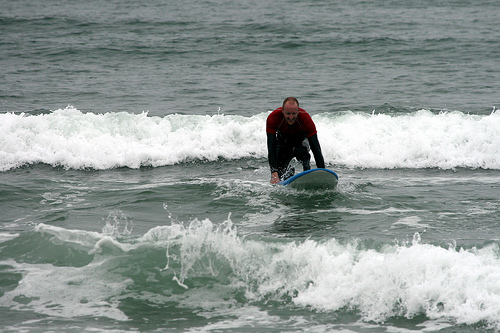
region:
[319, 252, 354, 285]
WHITE SEA FOAM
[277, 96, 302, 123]
MAN'S BALD HEAD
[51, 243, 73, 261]
GREEN GREY SEA WATER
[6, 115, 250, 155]
BREAKING OCEAN WAVE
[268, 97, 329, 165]
MAN KNEELING IN CROUCHED POSITION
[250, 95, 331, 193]
MAN KNEELING IN CROUCHED POSITION ON SURF BOARD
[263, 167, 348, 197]
BLUE AND GREY SURF BOARD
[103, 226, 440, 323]
WAVE ROLLING INTO BEACH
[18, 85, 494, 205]
MAN SURFING IN THE OCEAN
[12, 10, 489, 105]
RIPPLES IN THE OCEAN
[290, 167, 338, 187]
blue stripe on front of surfboard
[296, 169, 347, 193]
white bottom of surfboard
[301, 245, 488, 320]
foamy white waves in front right of pictures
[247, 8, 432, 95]
blue grey water in upper right of photo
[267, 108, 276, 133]
man's right arm in red /black wetsuit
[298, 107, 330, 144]
man's left arm in red /black wetsuit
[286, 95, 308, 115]
man with receding hairline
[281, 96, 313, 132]
man's smiling face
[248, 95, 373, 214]
smiling man kneeling on surfboard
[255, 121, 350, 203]
red and black wetsuit worn by man on surfboard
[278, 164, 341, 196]
a blue and white surfboard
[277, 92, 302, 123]
the balding head of a man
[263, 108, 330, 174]
a red and black wetsuit on a man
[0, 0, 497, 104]
dark ocean water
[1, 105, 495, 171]
a white wave rolling in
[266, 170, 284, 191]
a bare hand holding a surfboard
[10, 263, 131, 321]
white foam on the water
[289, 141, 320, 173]
the bent knee of a surfer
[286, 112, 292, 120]
the nose of a surfer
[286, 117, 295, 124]
the smiling mouth of a surfer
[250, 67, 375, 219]
Man surfing on the ocean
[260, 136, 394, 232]
Surfboard is white and blue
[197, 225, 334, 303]
White cap on ocean waves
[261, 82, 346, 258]
Man wearing full body wetsuit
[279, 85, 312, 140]
Man is going bald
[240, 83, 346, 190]
Surfer is trying to stand on the board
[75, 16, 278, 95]
Background of ocean is flat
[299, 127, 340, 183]
Man wearing long sleeves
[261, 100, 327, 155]
Red short sleeve on man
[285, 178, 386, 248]
Shadow from the surfboard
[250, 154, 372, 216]
a blue and white surfboard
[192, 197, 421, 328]
white wave caps on the water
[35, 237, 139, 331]
foamy white water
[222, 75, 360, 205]
a man standing on a surfboard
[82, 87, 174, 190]
white waves crashing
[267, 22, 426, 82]
deep blue ocean rippling waves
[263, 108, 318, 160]
red wet suit top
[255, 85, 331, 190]
black and red wet suit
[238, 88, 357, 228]
a man in the ocean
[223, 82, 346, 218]
a surfboard on top of the water